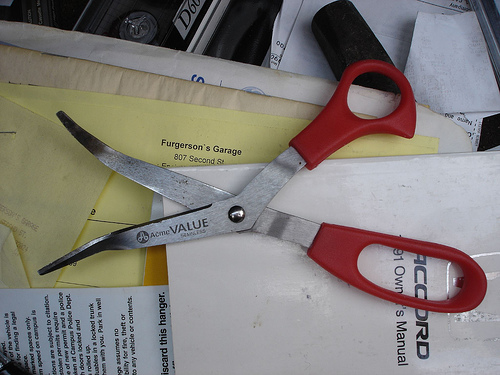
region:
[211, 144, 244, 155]
the word Garage on a paper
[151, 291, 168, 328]
the word hanger on a paper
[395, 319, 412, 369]
the word Manual on a paper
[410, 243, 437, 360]
the word ACCORD on a paper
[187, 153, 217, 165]
the word Second on a paper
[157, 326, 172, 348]
the word this on a paper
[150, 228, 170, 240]
the Acme Garage on a pair of scissors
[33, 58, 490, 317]
a red pair of scissors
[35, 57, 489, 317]
a red pair of broken scissors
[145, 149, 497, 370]
White sheet of paper reading Owner's Manual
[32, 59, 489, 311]
Pair of red handled scissors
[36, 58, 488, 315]
Scissors with bent tips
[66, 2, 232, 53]
Black and white cassette tape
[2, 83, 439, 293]
Yellow paper with the heading Furgerson's Garage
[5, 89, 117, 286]
Faded receipt with staple at top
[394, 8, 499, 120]
Folded over white paper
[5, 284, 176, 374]
White paper with the last word reading hanger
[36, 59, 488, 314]
Scissors with the words Acme Value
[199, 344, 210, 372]
Red scissors on the white book.Red scissors on the white book.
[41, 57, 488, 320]
A pair of scissors on some paper.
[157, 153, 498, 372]
A white owner's manual.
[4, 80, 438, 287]
A yellow piece of paper.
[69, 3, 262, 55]
A cassette tape.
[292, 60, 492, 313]
Red handles of a pair of scissors.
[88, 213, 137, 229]
Black line on yellow paper.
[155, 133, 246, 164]
Yellow piece of paper that says Furgerson's Garage.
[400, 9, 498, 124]
A white folded over piece of paper.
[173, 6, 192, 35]
The letter D.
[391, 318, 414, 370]
The word Manual.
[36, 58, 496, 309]
The scissors are open.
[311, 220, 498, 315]
The handle is red.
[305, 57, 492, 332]
The scissors has one big openning and one small.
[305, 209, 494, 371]
The scissors is on top of the manual.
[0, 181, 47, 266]
The receipt is yellow.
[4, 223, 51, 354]
The receipt is next to the white paper.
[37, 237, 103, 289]
The edge of the scissors are bent.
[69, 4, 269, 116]
The VHS is next to the paper.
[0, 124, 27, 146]
The receipt has a staple.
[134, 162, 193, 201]
The scissors is made out of metal.